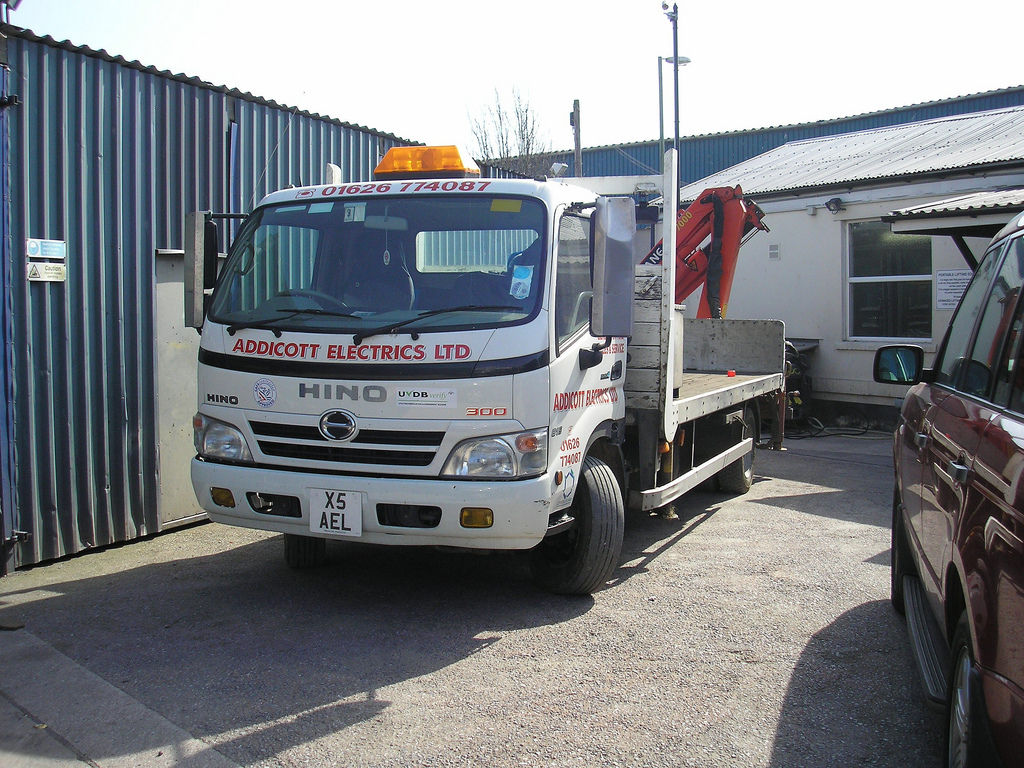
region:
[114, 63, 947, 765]
this is a work truck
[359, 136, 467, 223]
the light is orange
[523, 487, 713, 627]
the tire is black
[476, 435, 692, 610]
the tire is rubber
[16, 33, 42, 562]
metal rib on tin shed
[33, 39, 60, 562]
metal rib on tin shed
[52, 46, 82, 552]
metal rib on tin shed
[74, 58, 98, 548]
metal rib on tin shed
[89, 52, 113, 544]
metal rib on tin shed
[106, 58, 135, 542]
metal rib on tin shed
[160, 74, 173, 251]
metal rib on tin shed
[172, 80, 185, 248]
metal rib on tin shed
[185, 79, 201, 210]
metal rib on tin shed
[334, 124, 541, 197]
Light on top the white truck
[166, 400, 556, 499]
Headlight on the front of the truck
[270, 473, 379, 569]
License on the front of the bumper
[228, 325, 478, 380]
Sign on the front of the truck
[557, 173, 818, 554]
Bed on the back of the truck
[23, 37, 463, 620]
Corrugated building on the side of the building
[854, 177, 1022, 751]
SUV parked in front of the building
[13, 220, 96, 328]
Sign on the side of the building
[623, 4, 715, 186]
Pole hanging over the white utility truck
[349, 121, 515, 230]
Yellow light on top of truck.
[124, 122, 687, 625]
White truck with red lettering.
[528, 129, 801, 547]
Flatbed with wood wall on truck.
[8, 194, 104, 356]
Small signs on metal shed.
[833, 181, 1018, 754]
Maroon colored truck parked near white truck.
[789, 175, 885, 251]
Outdoor lighting above window on building.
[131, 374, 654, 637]
Wheels turned tight on truck.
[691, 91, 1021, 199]
Metal roof on top of white building.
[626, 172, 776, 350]
Tractor arm behind truck.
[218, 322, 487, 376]
the text is red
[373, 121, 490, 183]
an orange light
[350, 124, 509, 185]
there is an orange light on the cab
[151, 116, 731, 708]
a white truck cab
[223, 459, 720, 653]
the wheels are turned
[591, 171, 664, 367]
a large side view mirror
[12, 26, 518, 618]
the wall is corrugated metal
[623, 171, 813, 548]
this is a trailer bed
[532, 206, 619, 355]
a window on the truck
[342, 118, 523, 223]
a light on the truck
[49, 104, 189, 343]
blue sliding ont he building